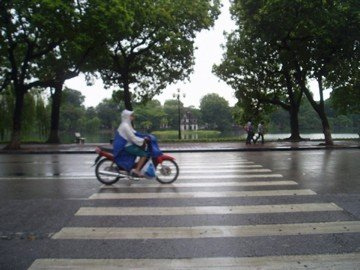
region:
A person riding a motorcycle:
[93, 108, 177, 182]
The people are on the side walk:
[1, 141, 357, 150]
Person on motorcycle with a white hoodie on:
[116, 106, 142, 144]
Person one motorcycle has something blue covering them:
[111, 132, 157, 170]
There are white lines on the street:
[27, 151, 356, 267]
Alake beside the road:
[62, 129, 356, 139]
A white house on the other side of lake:
[178, 110, 198, 129]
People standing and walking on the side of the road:
[72, 120, 263, 143]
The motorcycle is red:
[93, 145, 173, 163]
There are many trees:
[1, 1, 358, 140]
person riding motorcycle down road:
[89, 101, 184, 182]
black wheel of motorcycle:
[154, 161, 180, 184]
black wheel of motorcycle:
[93, 158, 116, 186]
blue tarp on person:
[116, 129, 153, 163]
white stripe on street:
[64, 197, 340, 217]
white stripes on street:
[90, 128, 282, 269]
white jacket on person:
[113, 108, 138, 146]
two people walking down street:
[239, 112, 266, 145]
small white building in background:
[179, 111, 197, 129]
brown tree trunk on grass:
[42, 80, 69, 146]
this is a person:
[100, 90, 158, 189]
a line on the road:
[55, 219, 132, 242]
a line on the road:
[153, 219, 343, 233]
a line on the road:
[208, 184, 317, 199]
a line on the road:
[196, 151, 294, 175]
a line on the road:
[77, 180, 165, 208]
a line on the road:
[171, 207, 291, 240]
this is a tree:
[305, 37, 356, 140]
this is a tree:
[219, 40, 312, 156]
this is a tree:
[16, 53, 84, 163]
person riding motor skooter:
[94, 101, 185, 192]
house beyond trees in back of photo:
[157, 106, 216, 135]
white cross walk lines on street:
[19, 148, 359, 267]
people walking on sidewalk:
[239, 117, 273, 147]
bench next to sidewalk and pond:
[70, 128, 89, 148]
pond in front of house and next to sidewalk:
[30, 127, 359, 143]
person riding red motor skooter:
[91, 106, 179, 184]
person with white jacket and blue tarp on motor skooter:
[88, 107, 186, 189]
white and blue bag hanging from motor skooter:
[139, 156, 162, 182]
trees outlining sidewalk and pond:
[1, 40, 357, 142]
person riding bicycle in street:
[82, 100, 187, 189]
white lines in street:
[18, 149, 356, 268]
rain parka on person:
[108, 105, 143, 173]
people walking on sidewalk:
[237, 113, 271, 149]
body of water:
[241, 125, 358, 137]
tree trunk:
[275, 102, 313, 142]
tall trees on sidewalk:
[212, 51, 359, 147]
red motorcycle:
[90, 133, 186, 189]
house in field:
[161, 110, 214, 133]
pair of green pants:
[123, 141, 154, 162]